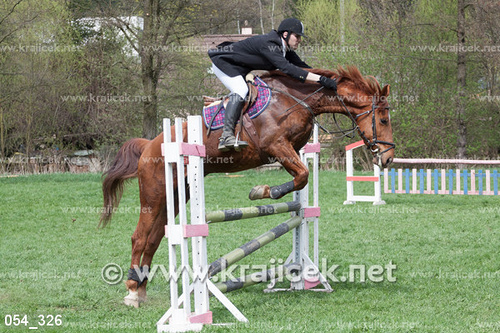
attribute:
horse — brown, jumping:
[96, 64, 397, 312]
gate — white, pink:
[153, 114, 333, 331]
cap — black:
[276, 16, 305, 51]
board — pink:
[178, 140, 207, 159]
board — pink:
[185, 222, 211, 239]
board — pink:
[303, 207, 320, 220]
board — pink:
[300, 144, 322, 154]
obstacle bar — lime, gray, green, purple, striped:
[203, 202, 299, 224]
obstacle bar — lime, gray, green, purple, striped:
[209, 215, 301, 278]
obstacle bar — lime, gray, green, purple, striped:
[206, 262, 294, 299]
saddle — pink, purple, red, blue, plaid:
[200, 73, 272, 130]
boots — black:
[216, 92, 251, 153]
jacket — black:
[208, 33, 312, 86]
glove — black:
[317, 74, 336, 93]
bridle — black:
[363, 96, 398, 161]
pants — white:
[208, 62, 248, 96]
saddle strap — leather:
[237, 117, 270, 163]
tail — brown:
[99, 135, 152, 232]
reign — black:
[332, 96, 375, 149]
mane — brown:
[298, 63, 381, 89]